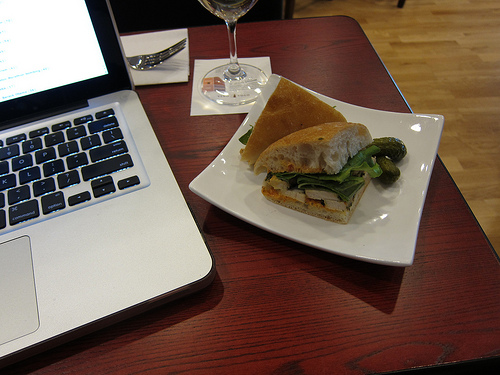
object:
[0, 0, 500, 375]
room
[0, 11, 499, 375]
desk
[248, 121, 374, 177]
bun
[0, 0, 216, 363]
laptop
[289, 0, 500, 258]
floor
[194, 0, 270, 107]
glass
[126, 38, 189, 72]
fork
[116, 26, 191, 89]
napkin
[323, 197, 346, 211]
chicken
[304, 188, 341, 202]
chicken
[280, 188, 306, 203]
chicken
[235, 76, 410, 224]
lunch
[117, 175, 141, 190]
keys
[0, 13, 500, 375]
table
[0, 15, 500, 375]
wall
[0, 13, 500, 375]
wood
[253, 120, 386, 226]
sandwich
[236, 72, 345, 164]
sandwich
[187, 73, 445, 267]
plate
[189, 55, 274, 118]
napkin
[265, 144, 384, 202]
lettuce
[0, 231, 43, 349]
mouse pad